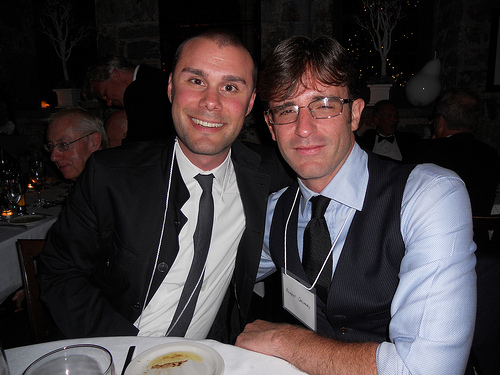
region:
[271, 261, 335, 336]
Laminated white name tag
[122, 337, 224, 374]
Food plate with remnants on it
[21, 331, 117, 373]
Top rim of a glass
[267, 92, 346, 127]
Man squinting behind glasses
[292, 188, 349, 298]
Black tie on blue button-up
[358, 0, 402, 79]
White decorative tree in background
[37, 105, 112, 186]
Old man with glasses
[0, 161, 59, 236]
Table with glasses and candles on it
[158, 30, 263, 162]
Man smiling for a picture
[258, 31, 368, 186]
Man trying to smile for picture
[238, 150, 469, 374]
A dark grey vest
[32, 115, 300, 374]
A dark black blazer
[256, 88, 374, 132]
A pair of silver framed glasses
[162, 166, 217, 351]
A black tie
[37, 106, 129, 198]
An older gentleman with glasses in the back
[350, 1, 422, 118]
A white tree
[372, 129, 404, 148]
A black bow tie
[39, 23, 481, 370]
Two very nice dressed men, smiling.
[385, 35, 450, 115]
A huge pear sculpture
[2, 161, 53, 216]
Wine glasses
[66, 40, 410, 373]
two friends at a party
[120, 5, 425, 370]
two men meeting at a social event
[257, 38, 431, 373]
man wearing a name tag in a suit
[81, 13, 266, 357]
man smiling at a party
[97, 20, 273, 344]
smiling man in a suit and tie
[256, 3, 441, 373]
man with blue shirt, black vest and tie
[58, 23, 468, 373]
two men finished eating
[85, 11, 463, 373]
two men at a meet up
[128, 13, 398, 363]
two men wearing name tags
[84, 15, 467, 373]
two happy people at a party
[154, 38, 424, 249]
two men are smiling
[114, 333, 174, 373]
the plate is dirty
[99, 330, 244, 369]
the plate is white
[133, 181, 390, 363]
they have nametags on their necks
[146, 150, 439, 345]
they are both wearing ties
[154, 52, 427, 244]
one man has glasses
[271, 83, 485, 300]
this man wears a vest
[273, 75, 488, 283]
this man wears a blue shirt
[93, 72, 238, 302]
this man wears a suit jacket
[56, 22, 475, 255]
they are at a wedding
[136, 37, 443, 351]
two men sitting at a table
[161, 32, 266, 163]
a man smiling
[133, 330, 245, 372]
an empty white plate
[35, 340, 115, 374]
the top of a glass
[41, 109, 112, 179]
balding man wearing glasses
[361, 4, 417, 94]
white tree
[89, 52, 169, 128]
man wearing a black suit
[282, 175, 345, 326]
a white badge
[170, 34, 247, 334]
a man wearing a black tie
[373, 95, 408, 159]
a man wearing a bow tie